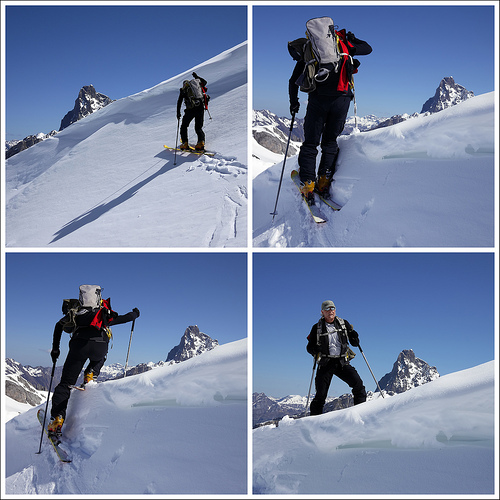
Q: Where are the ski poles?
A: In the skier's hands.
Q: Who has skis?
A: The skier.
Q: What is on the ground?
A: Snow.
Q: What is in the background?
A: Mountains.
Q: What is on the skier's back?
A: A backpack.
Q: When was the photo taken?
A: Daytime.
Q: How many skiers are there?
A: One.